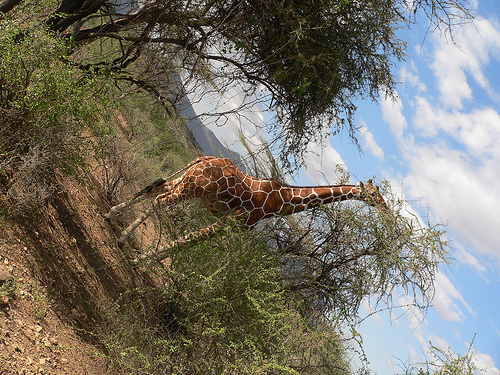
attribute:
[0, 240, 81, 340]
stones — small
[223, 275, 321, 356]
plants — green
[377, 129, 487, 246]
clouds — white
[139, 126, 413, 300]
giraffe — brown, white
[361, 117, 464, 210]
clouds — white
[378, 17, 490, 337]
sky — blue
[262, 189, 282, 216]
spot — brown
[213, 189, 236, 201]
spot — brown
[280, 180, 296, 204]
spot — brown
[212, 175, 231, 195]
spot — brown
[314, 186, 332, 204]
spot — brown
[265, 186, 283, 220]
spot — brown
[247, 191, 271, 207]
spot — brown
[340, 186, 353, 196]
spot — brown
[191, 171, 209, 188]
spot — brown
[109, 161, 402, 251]
giraffe — white, brown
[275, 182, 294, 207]
spot — brown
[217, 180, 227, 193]
spot — brown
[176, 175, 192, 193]
spot — brown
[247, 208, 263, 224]
spot — brown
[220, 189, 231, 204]
spot — brown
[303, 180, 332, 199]
spot — brown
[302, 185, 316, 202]
spot — brown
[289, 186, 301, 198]
spot — brown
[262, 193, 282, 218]
spot — brown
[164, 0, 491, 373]
sky — blue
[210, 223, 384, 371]
plants — some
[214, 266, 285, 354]
leaves — green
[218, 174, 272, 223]
fur — brown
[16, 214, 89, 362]
sand — brown